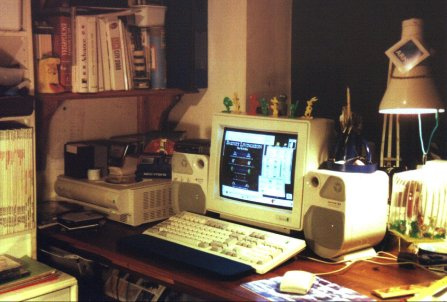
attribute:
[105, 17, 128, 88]
book — white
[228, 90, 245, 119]
figure — action, yellow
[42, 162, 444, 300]
table — wooden 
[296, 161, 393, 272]
speaker — white, big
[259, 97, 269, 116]
figurine — green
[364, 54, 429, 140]
light — metal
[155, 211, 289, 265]
keys — white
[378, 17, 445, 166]
lamp — on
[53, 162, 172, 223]
machine — ELECTRONIC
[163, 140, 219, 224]
speaker — white, large, sub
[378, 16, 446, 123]
lamp — white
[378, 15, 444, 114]
lamp — white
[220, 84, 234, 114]
figure — green, action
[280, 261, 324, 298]
mouse — computer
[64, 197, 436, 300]
desk — cluttered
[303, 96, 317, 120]
figurine — yellow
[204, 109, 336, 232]
monitor — on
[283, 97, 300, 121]
figurine — green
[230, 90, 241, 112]
figurine — yellow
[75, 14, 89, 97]
book — white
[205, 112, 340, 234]
computer monitor — tan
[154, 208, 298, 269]
keyboard — white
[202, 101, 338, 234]
computer monitor — on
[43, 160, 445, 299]
desk — large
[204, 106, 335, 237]
computer — white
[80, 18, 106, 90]
book — white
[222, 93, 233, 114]
figurine — green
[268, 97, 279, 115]
figurine — yellow